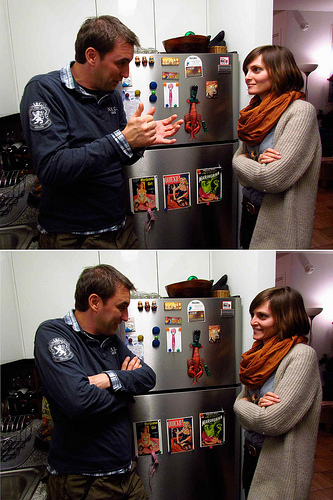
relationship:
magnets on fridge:
[132, 54, 232, 136] [128, 50, 244, 248]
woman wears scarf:
[237, 43, 320, 244] [233, 90, 305, 141]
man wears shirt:
[22, 12, 180, 248] [21, 63, 129, 230]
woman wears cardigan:
[237, 43, 320, 244] [240, 97, 320, 247]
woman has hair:
[237, 43, 320, 244] [240, 47, 303, 92]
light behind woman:
[301, 60, 319, 101] [237, 43, 320, 244]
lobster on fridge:
[183, 82, 205, 141] [128, 50, 244, 248]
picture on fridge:
[167, 86, 179, 107] [128, 50, 244, 248]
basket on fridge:
[163, 34, 212, 52] [128, 50, 244, 248]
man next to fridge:
[22, 12, 180, 248] [128, 50, 244, 248]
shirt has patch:
[21, 63, 129, 230] [27, 101, 52, 130]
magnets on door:
[134, 57, 157, 64] [111, 54, 237, 138]